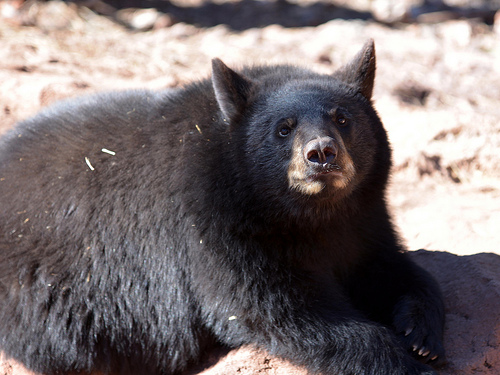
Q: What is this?
A: Bear.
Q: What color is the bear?
A: Black.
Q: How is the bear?
A: Motionless.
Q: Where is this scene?
A: At the zoo.